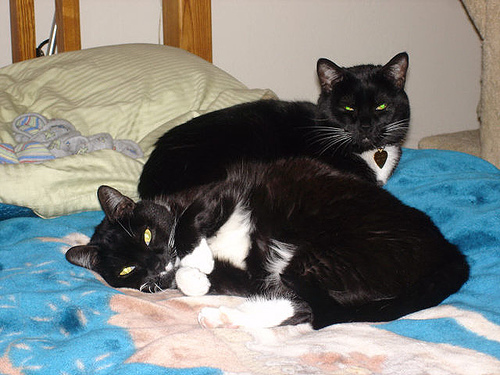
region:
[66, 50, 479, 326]
two cats laying down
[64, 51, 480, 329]
black and white cats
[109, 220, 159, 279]
two bright yellow eyes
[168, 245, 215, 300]
front paws are white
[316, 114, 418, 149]
white whiskers coming off the face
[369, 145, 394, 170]
collar hanging down the chest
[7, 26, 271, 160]
green pillow laying on the bed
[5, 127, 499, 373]
fuzzy blue blanket on the bed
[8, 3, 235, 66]
three wooden posts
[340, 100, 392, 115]
two small eyes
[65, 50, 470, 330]
two black and white cats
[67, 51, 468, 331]
two tuxedo cats on a bed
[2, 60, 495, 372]
bed with a blue and white blanket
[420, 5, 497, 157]
beige rug-covered cat tree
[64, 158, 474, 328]
black and white cat that is laying on bed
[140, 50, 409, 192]
black and white cat with hear-shaped tag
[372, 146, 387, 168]
heart-shaped tag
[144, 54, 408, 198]
black and white cat that is sitting on the bed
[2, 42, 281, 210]
pillow with the yellow-striped pillow case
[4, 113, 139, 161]
blue pink and white piece of clothing on the pillow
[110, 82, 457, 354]
two cats on blanket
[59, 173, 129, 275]
cats have black ears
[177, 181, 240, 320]
cat has white paws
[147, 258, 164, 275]
cat has black news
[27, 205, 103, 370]
blue and pink blanket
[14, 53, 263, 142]
white striped pillow behind cats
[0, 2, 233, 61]
brown wooden frame behind cats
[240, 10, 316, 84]
white wall behind cats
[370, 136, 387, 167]
heart shaped pendant on cat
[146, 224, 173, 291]
white spot on cat's mouth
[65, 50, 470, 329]
the two cats lying down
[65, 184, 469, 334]
the cat lying down on the bed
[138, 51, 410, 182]
the cat lying down on the bed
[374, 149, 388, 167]
the tag hanging from the cats neck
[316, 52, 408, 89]
the two ears on the cat's head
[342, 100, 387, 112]
the two eyes on the cat's head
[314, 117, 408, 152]
the whiskers sticking out from the cat's face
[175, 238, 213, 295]
the white ends of the cat's two front paws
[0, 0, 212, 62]
the wooden headboard against the wall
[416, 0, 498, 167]
the cat post to the right of the cats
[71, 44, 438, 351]
two cats on a bed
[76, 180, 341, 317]
black and white cat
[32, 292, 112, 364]
blue blanket under cats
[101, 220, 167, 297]
eyes of the cat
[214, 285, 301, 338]
white paws of the cat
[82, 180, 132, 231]
ear of the cat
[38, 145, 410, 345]
cat looking towards the camera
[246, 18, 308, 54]
wall behind the cats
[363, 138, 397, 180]
collar around cat's neck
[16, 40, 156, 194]
pillow on the bed